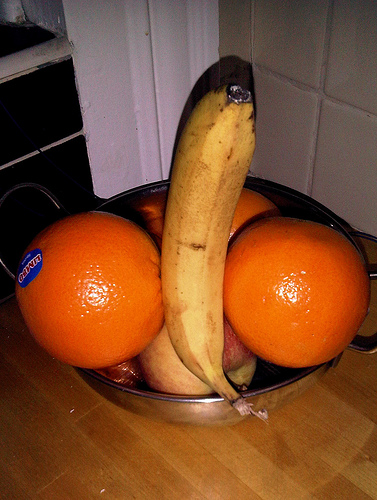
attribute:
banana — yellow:
[160, 82, 255, 424]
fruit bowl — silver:
[56, 175, 375, 426]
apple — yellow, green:
[141, 301, 256, 400]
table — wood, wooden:
[0, 225, 373, 499]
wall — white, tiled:
[220, 2, 375, 239]